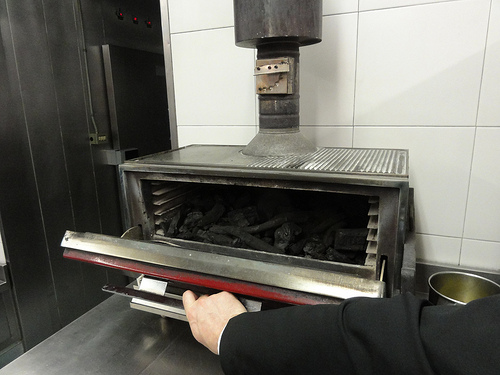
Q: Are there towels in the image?
A: No, there are no towels.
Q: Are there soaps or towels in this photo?
A: No, there are no towels or soaps.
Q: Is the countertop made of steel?
A: Yes, the countertop is made of steel.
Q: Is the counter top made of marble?
A: No, the counter top is made of steel.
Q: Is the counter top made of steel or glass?
A: The counter top is made of steel.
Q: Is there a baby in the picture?
A: No, there are no babies.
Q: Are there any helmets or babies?
A: No, there are no babies or helmets.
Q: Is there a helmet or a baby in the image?
A: No, there are no babies or helmets.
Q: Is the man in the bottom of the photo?
A: Yes, the man is in the bottom of the image.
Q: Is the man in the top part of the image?
A: No, the man is in the bottom of the image.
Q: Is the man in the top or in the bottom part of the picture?
A: The man is in the bottom of the image.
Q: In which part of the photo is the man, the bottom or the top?
A: The man is in the bottom of the image.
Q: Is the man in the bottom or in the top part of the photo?
A: The man is in the bottom of the image.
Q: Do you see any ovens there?
A: Yes, there is an oven.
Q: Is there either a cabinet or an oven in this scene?
A: Yes, there is an oven.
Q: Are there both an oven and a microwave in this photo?
A: No, there is an oven but no microwaves.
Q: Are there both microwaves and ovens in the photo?
A: No, there is an oven but no microwaves.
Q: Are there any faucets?
A: No, there are no faucets.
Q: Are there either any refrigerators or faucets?
A: No, there are no faucets or refrigerators.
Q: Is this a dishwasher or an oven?
A: This is an oven.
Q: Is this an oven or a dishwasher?
A: This is an oven.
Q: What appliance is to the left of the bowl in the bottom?
A: The appliance is an oven.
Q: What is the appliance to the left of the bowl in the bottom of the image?
A: The appliance is an oven.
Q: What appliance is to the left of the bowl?
A: The appliance is an oven.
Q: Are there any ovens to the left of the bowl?
A: Yes, there is an oven to the left of the bowl.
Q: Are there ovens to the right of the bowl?
A: No, the oven is to the left of the bowl.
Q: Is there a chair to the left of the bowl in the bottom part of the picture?
A: No, there is an oven to the left of the bowl.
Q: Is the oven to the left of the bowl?
A: Yes, the oven is to the left of the bowl.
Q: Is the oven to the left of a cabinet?
A: No, the oven is to the left of the bowl.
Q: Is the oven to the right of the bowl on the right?
A: No, the oven is to the left of the bowl.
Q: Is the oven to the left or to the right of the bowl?
A: The oven is to the left of the bowl.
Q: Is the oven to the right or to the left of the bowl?
A: The oven is to the left of the bowl.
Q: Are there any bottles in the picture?
A: No, there are no bottles.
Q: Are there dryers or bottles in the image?
A: No, there are no bottles or dryers.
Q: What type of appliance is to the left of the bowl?
A: The appliance is a cooker.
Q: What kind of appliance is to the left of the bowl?
A: The appliance is a cooker.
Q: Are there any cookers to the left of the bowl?
A: Yes, there is a cooker to the left of the bowl.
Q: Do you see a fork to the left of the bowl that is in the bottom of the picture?
A: No, there is a cooker to the left of the bowl.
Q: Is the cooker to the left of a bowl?
A: Yes, the cooker is to the left of a bowl.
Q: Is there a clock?
A: No, there are no clocks.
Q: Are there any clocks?
A: No, there are no clocks.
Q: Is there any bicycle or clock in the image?
A: No, there are no clocks or bicycles.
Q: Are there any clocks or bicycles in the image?
A: No, there are no clocks or bicycles.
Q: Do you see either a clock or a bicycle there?
A: No, there are no clocks or bicycles.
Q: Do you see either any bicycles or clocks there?
A: No, there are no clocks or bicycles.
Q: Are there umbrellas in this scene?
A: No, there are no umbrellas.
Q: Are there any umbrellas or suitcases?
A: No, there are no umbrellas or suitcases.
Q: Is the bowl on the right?
A: Yes, the bowl is on the right of the image.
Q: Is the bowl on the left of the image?
A: No, the bowl is on the right of the image.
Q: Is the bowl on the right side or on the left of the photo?
A: The bowl is on the right of the image.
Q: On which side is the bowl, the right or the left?
A: The bowl is on the right of the image.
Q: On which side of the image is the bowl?
A: The bowl is on the right of the image.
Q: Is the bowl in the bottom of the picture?
A: Yes, the bowl is in the bottom of the image.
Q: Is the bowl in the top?
A: No, the bowl is in the bottom of the image.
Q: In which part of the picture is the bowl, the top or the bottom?
A: The bowl is in the bottom of the image.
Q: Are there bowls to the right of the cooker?
A: Yes, there is a bowl to the right of the cooker.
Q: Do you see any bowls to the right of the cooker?
A: Yes, there is a bowl to the right of the cooker.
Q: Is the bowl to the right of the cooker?
A: Yes, the bowl is to the right of the cooker.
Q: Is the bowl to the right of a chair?
A: No, the bowl is to the right of the cooker.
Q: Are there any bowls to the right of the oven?
A: Yes, there is a bowl to the right of the oven.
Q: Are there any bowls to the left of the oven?
A: No, the bowl is to the right of the oven.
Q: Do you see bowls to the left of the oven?
A: No, the bowl is to the right of the oven.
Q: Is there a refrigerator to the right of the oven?
A: No, there is a bowl to the right of the oven.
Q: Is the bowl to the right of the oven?
A: Yes, the bowl is to the right of the oven.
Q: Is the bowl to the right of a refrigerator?
A: No, the bowl is to the right of the oven.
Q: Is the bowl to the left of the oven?
A: No, the bowl is to the right of the oven.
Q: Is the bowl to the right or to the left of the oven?
A: The bowl is to the right of the oven.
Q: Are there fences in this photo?
A: No, there are no fences.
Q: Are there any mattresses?
A: No, there are no mattresses.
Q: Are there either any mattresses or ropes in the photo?
A: No, there are no mattresses or ropes.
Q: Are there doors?
A: Yes, there is a door.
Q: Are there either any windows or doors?
A: Yes, there is a door.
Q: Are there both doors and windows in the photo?
A: No, there is a door but no windows.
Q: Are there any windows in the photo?
A: No, there are no windows.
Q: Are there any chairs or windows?
A: No, there are no windows or chairs.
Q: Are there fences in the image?
A: No, there are no fences.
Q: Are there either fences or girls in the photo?
A: No, there are no fences or girls.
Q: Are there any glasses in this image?
A: No, there are no glasses.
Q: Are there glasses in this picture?
A: No, there are no glasses.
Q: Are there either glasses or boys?
A: No, there are no glasses or boys.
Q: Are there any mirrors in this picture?
A: No, there are no mirrors.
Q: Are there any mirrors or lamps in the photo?
A: No, there are no mirrors or lamps.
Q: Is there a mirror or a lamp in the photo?
A: No, there are no mirrors or lamps.